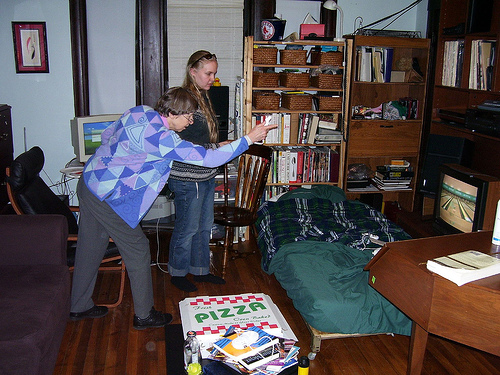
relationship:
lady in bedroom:
[156, 51, 228, 291] [0, 0, 500, 375]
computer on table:
[431, 168, 485, 234] [378, 227, 424, 291]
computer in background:
[80, 113, 115, 148] [45, 83, 151, 166]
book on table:
[434, 259, 499, 292] [378, 227, 424, 291]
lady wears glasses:
[61, 89, 281, 327] [172, 100, 212, 122]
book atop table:
[434, 259, 499, 292] [378, 227, 424, 291]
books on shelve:
[242, 70, 346, 149] [233, 79, 393, 235]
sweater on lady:
[115, 121, 168, 193] [99, 75, 148, 168]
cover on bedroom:
[296, 249, 358, 303] [79, 49, 418, 328]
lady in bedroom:
[61, 89, 281, 327] [0, 0, 500, 375]